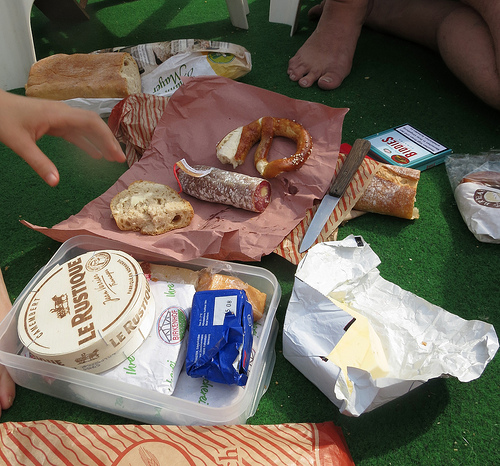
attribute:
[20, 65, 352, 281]
paper — brown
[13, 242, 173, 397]
container — round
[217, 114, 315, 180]
bread — brown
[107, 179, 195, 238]
bread — brown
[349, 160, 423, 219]
bread — brown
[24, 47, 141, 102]
bread — brown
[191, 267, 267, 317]
bread — brown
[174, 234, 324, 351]
container — plastic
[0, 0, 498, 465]
surface — green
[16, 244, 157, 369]
container — white, brown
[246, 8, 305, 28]
seats — white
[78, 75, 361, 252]
food — Blue , wrapped up 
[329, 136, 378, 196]
handle — brown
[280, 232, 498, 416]
wrapper — crumpled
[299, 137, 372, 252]
knife — wooden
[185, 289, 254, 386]
food — wrapped, blue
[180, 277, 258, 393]
food — blue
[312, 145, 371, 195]
handle — wooden 